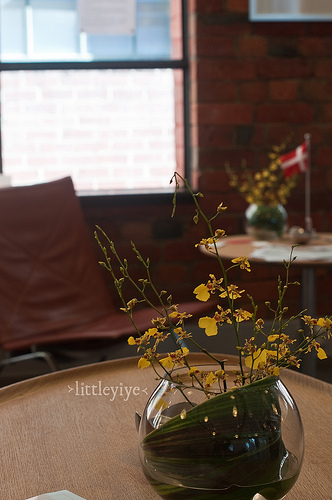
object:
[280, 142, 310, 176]
cross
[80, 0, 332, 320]
wall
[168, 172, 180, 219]
tip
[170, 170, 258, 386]
flower stem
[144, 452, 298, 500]
water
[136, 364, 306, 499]
vase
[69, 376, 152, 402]
stamp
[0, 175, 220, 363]
chair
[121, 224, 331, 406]
flowers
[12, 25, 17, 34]
sun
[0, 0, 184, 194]
window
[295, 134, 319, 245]
flagpole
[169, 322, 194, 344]
flower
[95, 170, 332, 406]
plant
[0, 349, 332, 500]
table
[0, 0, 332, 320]
background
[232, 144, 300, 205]
flowers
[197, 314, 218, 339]
petals